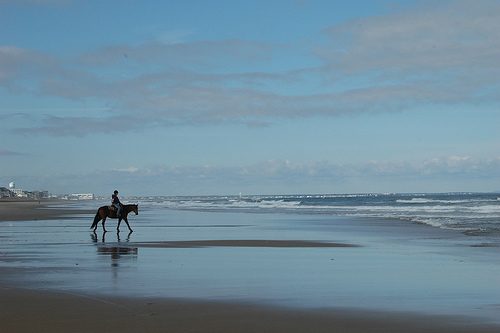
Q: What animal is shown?
A: Horse.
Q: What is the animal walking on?
A: Sand.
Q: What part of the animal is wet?
A: Hooves.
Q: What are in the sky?
A: Clouds.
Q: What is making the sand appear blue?
A: Water.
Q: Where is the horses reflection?
A: Wet sand.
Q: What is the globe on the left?
A: Water tower.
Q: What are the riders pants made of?
A: Denim.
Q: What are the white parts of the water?
A: Waves.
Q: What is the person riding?
A: A horse.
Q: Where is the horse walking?
A: On the sand.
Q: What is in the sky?
A: Clouds.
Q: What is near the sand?
A: Water.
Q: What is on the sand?
A: Water.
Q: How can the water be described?
A: Choppy.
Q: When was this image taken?
A: During the early evening.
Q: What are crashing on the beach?
A: Waves.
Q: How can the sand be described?
A: Wet.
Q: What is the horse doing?
A: Walking.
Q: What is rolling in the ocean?
A: Waves.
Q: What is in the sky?
A: Clouds.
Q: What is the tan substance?
A: Sand.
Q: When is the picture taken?
A: Daytime.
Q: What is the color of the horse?
A: Brown.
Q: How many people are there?
A: One.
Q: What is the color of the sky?
A: Blue.